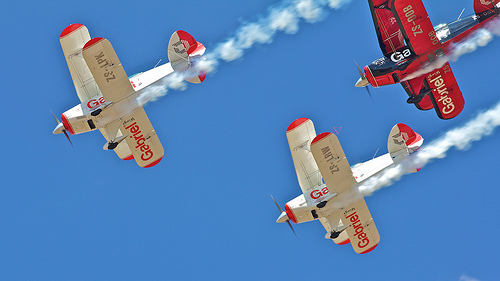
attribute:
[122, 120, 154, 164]
writing — red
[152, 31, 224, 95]
tail — white, red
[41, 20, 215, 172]
airplane — in formation , red, white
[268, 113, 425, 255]
airplane — in formation , red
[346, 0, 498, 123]
airplane — in formation 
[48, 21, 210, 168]
jet — red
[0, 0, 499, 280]
sky — blue, clear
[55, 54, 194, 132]
body — white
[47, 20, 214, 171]
plane — white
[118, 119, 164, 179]
writing — red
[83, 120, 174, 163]
wing — white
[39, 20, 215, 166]
white airplane — red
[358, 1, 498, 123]
plane — red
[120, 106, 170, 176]
branding — red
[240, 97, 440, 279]
airplane — white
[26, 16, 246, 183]
airplane — red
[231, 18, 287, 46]
smoke — white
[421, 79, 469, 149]
wing — red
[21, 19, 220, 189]
contrails — white